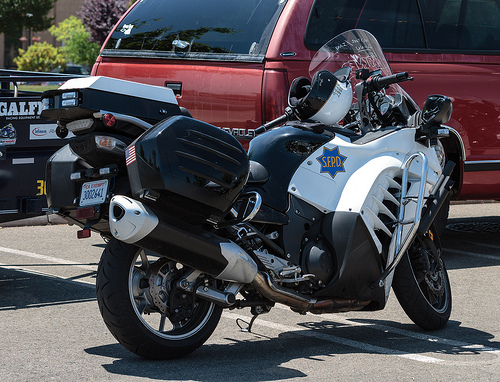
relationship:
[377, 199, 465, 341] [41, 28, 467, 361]
tire on bike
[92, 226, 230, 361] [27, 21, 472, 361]
tire on bike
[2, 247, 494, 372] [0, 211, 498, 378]
line on pavement